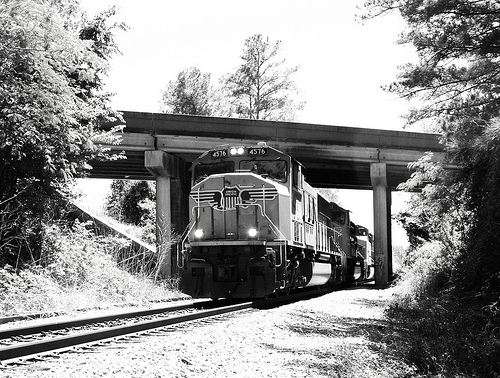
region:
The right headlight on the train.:
[244, 227, 256, 236]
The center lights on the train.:
[230, 148, 246, 154]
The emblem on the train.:
[187, 183, 276, 212]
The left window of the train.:
[192, 163, 237, 180]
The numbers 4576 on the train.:
[207, 147, 270, 159]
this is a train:
[137, 110, 382, 361]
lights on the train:
[178, 208, 275, 255]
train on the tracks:
[3, 25, 428, 370]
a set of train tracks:
[11, 265, 242, 375]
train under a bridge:
[66, 5, 458, 334]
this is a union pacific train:
[185, 169, 293, 239]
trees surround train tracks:
[0, 5, 496, 366]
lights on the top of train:
[213, 128, 261, 169]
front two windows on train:
[185, 142, 299, 203]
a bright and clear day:
[15, 6, 499, 353]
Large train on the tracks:
[179, 136, 368, 309]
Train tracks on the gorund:
[23, 307, 223, 348]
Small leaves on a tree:
[396, 279, 439, 318]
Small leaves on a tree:
[381, 206, 418, 237]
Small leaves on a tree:
[395, 161, 430, 200]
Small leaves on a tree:
[410, 152, 452, 201]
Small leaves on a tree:
[228, 38, 286, 66]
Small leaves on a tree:
[158, 69, 232, 109]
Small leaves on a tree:
[55, 54, 97, 127]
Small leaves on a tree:
[18, 125, 77, 163]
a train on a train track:
[146, 142, 371, 329]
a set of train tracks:
[11, 295, 222, 336]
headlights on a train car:
[188, 226, 265, 242]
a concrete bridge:
[109, 107, 439, 178]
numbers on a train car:
[248, 145, 269, 157]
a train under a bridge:
[140, 120, 385, 308]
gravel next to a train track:
[112, 315, 262, 375]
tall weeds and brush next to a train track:
[17, 235, 169, 315]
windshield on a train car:
[237, 155, 288, 186]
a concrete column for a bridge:
[358, 159, 393, 294]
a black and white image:
[2, 0, 489, 376]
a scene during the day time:
[4, 4, 499, 361]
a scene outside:
[8, 2, 495, 376]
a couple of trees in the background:
[142, 18, 309, 143]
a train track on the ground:
[0, 272, 378, 376]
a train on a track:
[155, 132, 405, 316]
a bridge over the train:
[30, 80, 478, 315]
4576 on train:
[247, 140, 274, 164]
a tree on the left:
[0, 0, 135, 291]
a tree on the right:
[357, 4, 499, 372]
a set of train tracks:
[30, 295, 193, 371]